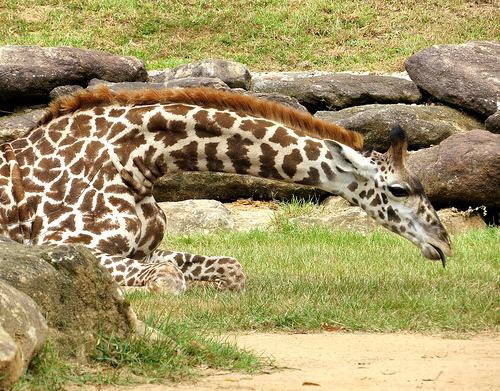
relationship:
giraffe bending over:
[9, 84, 424, 274] [0, 55, 435, 273]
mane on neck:
[68, 83, 332, 129] [126, 83, 356, 199]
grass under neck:
[197, 231, 365, 345] [126, 83, 356, 199]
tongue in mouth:
[426, 245, 454, 268] [410, 214, 476, 271]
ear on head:
[320, 131, 375, 184] [347, 128, 441, 258]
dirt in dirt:
[244, 324, 439, 390] [244, 324, 439, 390]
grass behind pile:
[197, 231, 365, 345] [244, 324, 439, 390]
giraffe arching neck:
[9, 84, 424, 274] [126, 83, 356, 199]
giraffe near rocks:
[9, 84, 424, 274] [1, 232, 101, 312]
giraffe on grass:
[9, 84, 424, 274] [197, 231, 365, 345]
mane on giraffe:
[68, 83, 332, 129] [9, 84, 424, 274]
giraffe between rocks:
[9, 84, 424, 274] [1, 232, 101, 312]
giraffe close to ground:
[9, 84, 424, 274] [257, 256, 499, 379]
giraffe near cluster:
[9, 84, 424, 274] [338, 43, 499, 177]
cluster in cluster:
[338, 43, 499, 177] [370, 65, 492, 158]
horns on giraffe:
[380, 117, 417, 170] [9, 84, 424, 274]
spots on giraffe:
[144, 113, 190, 150] [9, 84, 424, 274]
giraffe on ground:
[9, 84, 424, 274] [257, 256, 499, 379]